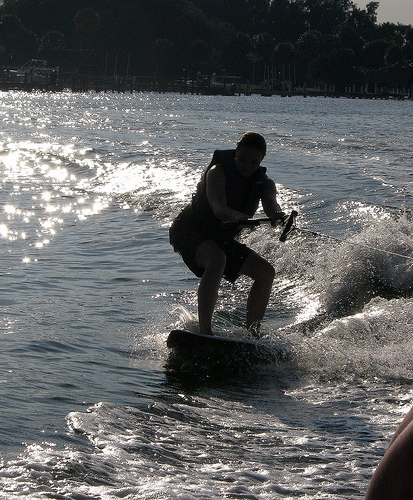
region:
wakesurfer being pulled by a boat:
[168, 133, 293, 367]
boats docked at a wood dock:
[2, 57, 63, 91]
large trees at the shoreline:
[0, 0, 411, 94]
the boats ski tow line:
[277, 210, 410, 272]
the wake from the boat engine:
[297, 196, 412, 385]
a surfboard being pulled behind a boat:
[166, 330, 278, 369]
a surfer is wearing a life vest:
[192, 149, 264, 244]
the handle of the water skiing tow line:
[279, 210, 300, 243]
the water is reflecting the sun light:
[1, 139, 195, 261]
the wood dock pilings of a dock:
[239, 77, 411, 97]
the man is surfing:
[168, 133, 291, 336]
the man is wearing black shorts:
[174, 223, 257, 272]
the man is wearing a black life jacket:
[192, 145, 280, 234]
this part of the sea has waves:
[200, 168, 410, 383]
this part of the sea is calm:
[143, 88, 412, 198]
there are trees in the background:
[8, 0, 408, 83]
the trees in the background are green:
[3, 0, 410, 92]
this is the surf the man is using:
[166, 331, 307, 377]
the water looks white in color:
[268, 239, 412, 414]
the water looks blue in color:
[156, 97, 411, 138]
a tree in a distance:
[183, 36, 210, 68]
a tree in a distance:
[141, 33, 171, 74]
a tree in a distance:
[41, 28, 68, 56]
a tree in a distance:
[75, 7, 106, 49]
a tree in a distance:
[4, 11, 41, 69]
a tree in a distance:
[272, 34, 296, 78]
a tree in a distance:
[327, 45, 360, 87]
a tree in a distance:
[371, 37, 383, 71]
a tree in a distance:
[279, 43, 291, 69]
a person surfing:
[119, 91, 324, 383]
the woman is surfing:
[154, 116, 311, 396]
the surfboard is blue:
[143, 285, 320, 398]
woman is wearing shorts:
[169, 219, 266, 285]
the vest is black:
[164, 159, 292, 251]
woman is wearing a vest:
[163, 156, 324, 258]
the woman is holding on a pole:
[191, 175, 370, 318]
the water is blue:
[16, 238, 105, 367]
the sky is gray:
[369, 7, 407, 28]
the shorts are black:
[165, 214, 349, 319]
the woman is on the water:
[170, 131, 334, 394]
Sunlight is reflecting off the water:
[3, 129, 174, 244]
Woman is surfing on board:
[159, 297, 281, 358]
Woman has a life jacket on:
[193, 121, 303, 251]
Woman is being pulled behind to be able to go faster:
[225, 202, 411, 290]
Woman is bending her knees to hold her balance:
[174, 217, 287, 297]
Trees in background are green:
[5, 7, 412, 73]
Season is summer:
[20, 45, 405, 461]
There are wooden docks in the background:
[3, 57, 410, 122]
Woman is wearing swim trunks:
[165, 149, 297, 297]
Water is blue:
[26, 97, 190, 342]